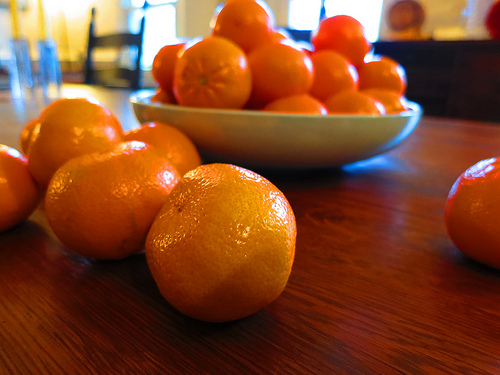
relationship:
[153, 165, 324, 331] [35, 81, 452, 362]
orange on table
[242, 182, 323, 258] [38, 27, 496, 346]
light on orange